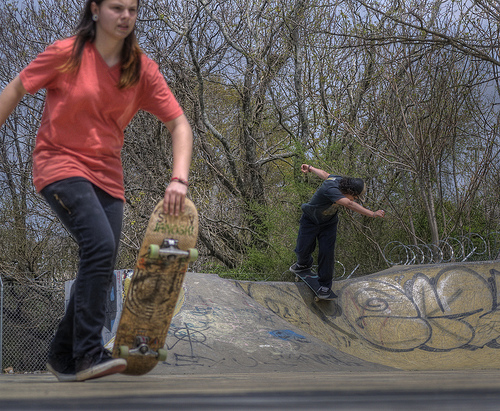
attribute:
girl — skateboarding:
[1, 0, 194, 381]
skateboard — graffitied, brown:
[111, 196, 200, 377]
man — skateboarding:
[289, 162, 384, 300]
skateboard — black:
[289, 262, 339, 305]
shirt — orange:
[21, 35, 186, 201]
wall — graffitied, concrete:
[64, 259, 498, 377]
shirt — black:
[301, 174, 346, 224]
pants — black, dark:
[38, 174, 127, 368]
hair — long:
[54, 0, 143, 90]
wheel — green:
[147, 242, 162, 263]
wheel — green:
[187, 246, 198, 262]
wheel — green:
[117, 346, 129, 359]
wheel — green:
[155, 346, 168, 362]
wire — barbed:
[330, 232, 498, 279]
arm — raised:
[299, 162, 331, 178]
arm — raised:
[338, 195, 385, 222]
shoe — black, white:
[41, 355, 79, 382]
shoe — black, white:
[72, 350, 129, 382]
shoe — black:
[289, 257, 314, 273]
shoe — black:
[316, 284, 332, 300]